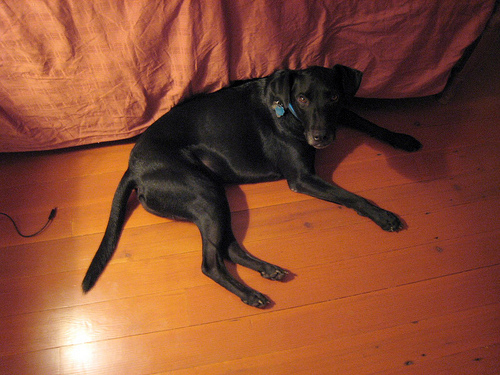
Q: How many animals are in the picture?
A: One.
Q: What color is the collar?
A: Blue.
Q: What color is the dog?
A: Black.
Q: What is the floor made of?
A: Wood.